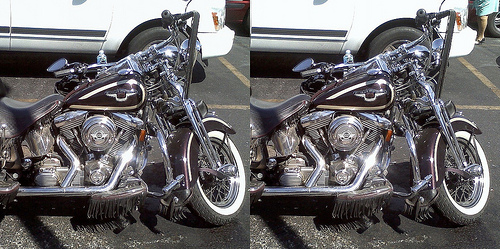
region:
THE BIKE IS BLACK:
[0, 9, 491, 234]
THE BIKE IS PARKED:
[0, 10, 493, 240]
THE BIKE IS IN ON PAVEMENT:
[0, 8, 494, 230]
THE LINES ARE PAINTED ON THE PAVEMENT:
[0, 48, 499, 117]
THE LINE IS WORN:
[185, 41, 498, 123]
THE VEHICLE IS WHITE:
[0, 0, 486, 61]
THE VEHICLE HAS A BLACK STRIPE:
[0, 25, 352, 47]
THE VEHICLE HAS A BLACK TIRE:
[110, 22, 448, 88]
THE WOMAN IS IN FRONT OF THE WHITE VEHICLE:
[471, 0, 498, 47]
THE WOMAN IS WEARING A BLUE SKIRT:
[471, 0, 498, 19]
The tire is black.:
[427, 123, 497, 208]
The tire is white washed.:
[430, 121, 496, 226]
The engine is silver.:
[311, 110, 391, 193]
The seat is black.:
[252, 85, 311, 138]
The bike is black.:
[296, 47, 428, 139]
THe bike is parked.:
[280, 40, 496, 245]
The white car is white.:
[265, 14, 470, 86]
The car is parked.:
[247, 1, 482, 69]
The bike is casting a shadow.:
[265, 189, 316, 246]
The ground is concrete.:
[448, 66, 496, 117]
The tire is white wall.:
[441, 112, 489, 237]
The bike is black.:
[320, 69, 402, 126]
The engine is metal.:
[308, 108, 421, 222]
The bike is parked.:
[268, 5, 473, 225]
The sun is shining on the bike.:
[253, 12, 490, 240]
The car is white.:
[254, 2, 493, 83]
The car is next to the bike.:
[268, 12, 465, 237]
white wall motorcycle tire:
[171, 119, 249, 229]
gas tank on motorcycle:
[54, 68, 155, 123]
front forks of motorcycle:
[143, 62, 243, 191]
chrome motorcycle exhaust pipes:
[2, 129, 144, 209]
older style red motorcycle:
[1, 7, 249, 234]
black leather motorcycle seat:
[2, 86, 72, 128]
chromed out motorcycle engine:
[43, 92, 149, 197]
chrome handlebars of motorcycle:
[43, 19, 210, 115]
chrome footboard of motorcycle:
[79, 160, 152, 225]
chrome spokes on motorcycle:
[193, 135, 241, 211]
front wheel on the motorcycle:
[432, 138, 496, 215]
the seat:
[257, 98, 290, 115]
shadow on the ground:
[257, 223, 302, 247]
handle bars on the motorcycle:
[395, 11, 439, 49]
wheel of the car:
[372, 33, 404, 50]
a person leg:
[477, 3, 489, 45]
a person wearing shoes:
[476, 37, 485, 49]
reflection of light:
[357, 153, 385, 175]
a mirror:
[294, 59, 327, 72]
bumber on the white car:
[459, 33, 480, 53]